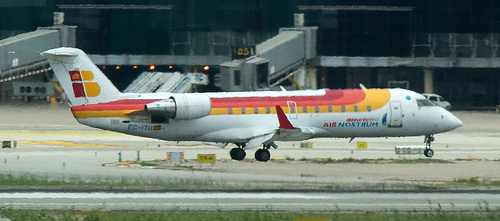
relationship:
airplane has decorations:
[39, 47, 463, 162] [65, 63, 397, 123]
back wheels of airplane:
[227, 140, 279, 167] [39, 47, 463, 162]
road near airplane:
[3, 188, 500, 213] [39, 47, 463, 162]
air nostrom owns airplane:
[322, 118, 383, 131] [39, 47, 463, 162]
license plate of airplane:
[121, 121, 168, 137] [39, 47, 463, 162]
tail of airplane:
[42, 35, 122, 101] [39, 47, 463, 162]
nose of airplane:
[415, 108, 464, 140] [39, 47, 463, 162]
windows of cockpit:
[415, 98, 445, 111] [408, 90, 449, 122]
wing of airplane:
[200, 106, 325, 150] [39, 47, 463, 162]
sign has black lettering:
[197, 152, 218, 165] [194, 152, 220, 165]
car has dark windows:
[420, 88, 452, 111] [429, 93, 447, 103]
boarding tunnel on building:
[214, 16, 330, 89] [1, 1, 499, 96]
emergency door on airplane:
[283, 96, 301, 120] [39, 47, 463, 162]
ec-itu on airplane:
[123, 122, 159, 135] [39, 47, 463, 162]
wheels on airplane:
[227, 141, 279, 164] [39, 47, 463, 162]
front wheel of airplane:
[418, 134, 442, 162] [39, 47, 463, 162]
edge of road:
[0, 184, 500, 191] [3, 188, 500, 213]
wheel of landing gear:
[255, 145, 272, 161] [226, 141, 279, 162]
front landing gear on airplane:
[418, 134, 442, 161] [39, 47, 463, 162]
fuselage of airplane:
[69, 84, 474, 143] [39, 47, 463, 162]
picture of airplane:
[1, 0, 499, 220] [39, 47, 463, 162]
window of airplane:
[364, 103, 375, 115] [39, 47, 463, 162]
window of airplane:
[339, 105, 348, 114] [39, 47, 463, 162]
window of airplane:
[326, 105, 337, 115] [39, 47, 463, 162]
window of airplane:
[314, 101, 323, 114] [39, 47, 463, 162]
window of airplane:
[301, 106, 310, 114] [39, 47, 463, 162]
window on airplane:
[265, 107, 272, 114] [39, 47, 463, 162]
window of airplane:
[251, 106, 261, 115] [39, 47, 463, 162]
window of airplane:
[240, 108, 249, 116] [39, 47, 463, 162]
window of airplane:
[227, 102, 234, 115] [39, 47, 463, 162]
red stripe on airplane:
[101, 84, 342, 104] [39, 47, 463, 162]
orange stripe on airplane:
[71, 90, 393, 121] [39, 47, 463, 162]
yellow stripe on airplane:
[76, 84, 396, 118] [39, 47, 463, 162]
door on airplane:
[387, 99, 407, 129] [39, 47, 463, 162]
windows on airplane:
[222, 99, 377, 116] [39, 47, 463, 162]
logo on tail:
[65, 66, 103, 100] [42, 35, 122, 101]